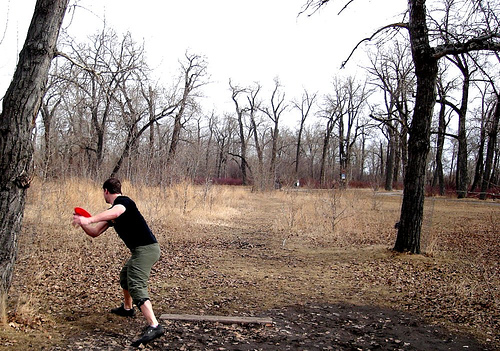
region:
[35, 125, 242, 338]
a man wearing a shirt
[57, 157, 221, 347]
a man wearing a black shirt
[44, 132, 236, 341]
a man wearing pants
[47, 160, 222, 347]
a man wearing shoes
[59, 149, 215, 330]
a man holding a freesbee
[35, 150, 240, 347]
a man holding a red freesbee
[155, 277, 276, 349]
plywood on the ground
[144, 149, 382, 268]
tall grass on the ground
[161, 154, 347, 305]
tall grass in a field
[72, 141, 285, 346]
man standing outside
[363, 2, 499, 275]
The tree is bare.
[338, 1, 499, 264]
The tree is leafless.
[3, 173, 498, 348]
The grass is dry.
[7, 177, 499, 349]
Brown leaves cover the ground.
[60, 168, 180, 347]
Man is holding frisbee.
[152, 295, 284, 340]
Board is laying on ground.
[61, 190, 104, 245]
The frisbee is red.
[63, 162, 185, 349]
Man is wearing shirt.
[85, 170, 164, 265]
The shirt is black.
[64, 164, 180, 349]
The man is wearing shoes.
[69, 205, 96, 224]
the red frisbee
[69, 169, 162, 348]
the man prepares to throw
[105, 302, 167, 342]
the mans black shoes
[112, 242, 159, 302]
the green cargo shorts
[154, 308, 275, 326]
wood on the ground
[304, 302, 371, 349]
leaves in the dirt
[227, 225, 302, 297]
leaves int he dead grass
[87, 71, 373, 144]
the trees are bare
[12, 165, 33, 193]
a knot on the tree trunk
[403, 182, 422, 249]
bark on the tree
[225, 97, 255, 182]
tree standing with no leaves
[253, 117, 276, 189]
tree standing with no leaves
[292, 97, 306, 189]
tree standing with no leaves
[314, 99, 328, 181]
tree standing with no leaves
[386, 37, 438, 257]
tree standing with no leaves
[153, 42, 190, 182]
tree standing with no leaves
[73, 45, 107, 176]
tree standing with no leaves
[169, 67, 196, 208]
tree standing with no leaves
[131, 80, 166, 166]
tree standing with no leaves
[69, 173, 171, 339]
man with red frisbee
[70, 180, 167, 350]
a young man throwing frisbee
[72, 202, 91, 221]
a red frisbee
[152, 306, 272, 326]
a brown plank of wood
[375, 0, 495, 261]
a tall bare tree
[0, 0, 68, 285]
a large tree trunk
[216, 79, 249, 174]
a tall bare tree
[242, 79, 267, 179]
a tall bare tree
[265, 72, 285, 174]
a tall bare tree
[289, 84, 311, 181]
a tall bare tree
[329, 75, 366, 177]
a tall bare tree